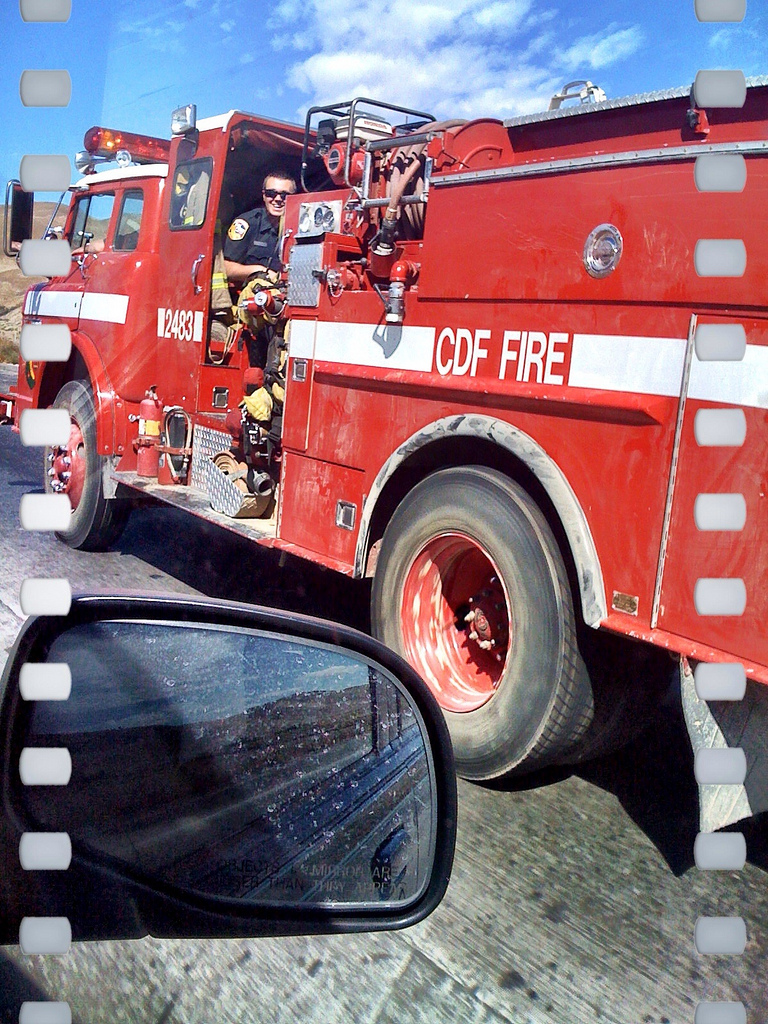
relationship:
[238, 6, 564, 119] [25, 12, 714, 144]
clouds in sky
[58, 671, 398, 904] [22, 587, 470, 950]
reflection on mirror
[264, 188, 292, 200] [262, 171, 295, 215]
glasses on face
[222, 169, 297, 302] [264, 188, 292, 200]
fireman wearing glasses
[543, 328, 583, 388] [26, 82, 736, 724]
letter on a firetruck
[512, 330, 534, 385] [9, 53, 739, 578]
letter on a firetruck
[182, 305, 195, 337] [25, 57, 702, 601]
letter on a firetruck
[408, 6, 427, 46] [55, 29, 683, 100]
clouds in sky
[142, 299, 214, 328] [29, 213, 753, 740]
number on a firetruck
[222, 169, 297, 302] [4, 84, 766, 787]
fireman on firetruck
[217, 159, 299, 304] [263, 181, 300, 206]
fireman wearing sunglasses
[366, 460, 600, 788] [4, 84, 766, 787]
tire on back of firetruck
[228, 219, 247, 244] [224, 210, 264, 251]
patch on shoulder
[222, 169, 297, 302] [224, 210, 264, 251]
fireman has shoulder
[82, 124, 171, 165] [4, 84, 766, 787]
light on top of firetruck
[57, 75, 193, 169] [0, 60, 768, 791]
light on firetruck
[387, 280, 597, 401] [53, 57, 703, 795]
writing on truck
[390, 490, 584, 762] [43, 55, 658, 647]
tire on truck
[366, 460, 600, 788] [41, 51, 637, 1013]
tire on truck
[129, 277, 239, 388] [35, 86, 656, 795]
numbers on truck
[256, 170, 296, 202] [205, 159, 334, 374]
glasses on face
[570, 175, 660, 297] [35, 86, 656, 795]
tank on truck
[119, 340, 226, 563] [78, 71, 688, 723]
extinguisher on truck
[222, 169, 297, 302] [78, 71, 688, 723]
fireman on truck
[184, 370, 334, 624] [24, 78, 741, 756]
kit on truck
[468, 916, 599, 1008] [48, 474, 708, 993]
stains on ground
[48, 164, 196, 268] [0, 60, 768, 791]
windows on firetruck